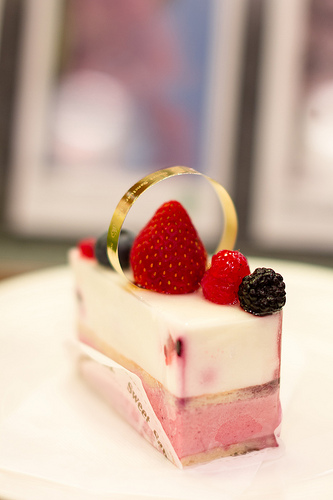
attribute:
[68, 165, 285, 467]
cake — pink, layered, rectangular, white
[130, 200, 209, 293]
stawberry — red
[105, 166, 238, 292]
gold ring — engraved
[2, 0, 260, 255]
picture — framed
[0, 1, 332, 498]
background — blurry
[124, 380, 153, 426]
sweet — gold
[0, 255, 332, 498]
plate — round